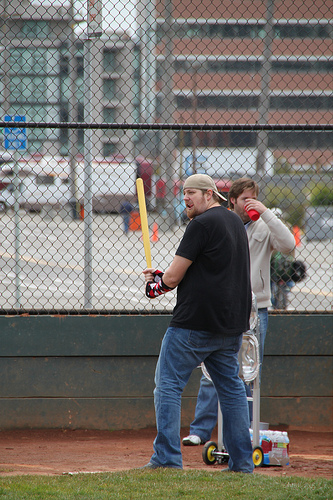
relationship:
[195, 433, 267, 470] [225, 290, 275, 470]
wheel on a dolly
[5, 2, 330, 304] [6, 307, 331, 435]
fence over a wall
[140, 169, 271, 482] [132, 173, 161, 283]
guy holding bat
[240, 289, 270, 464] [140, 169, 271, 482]
handtruck behind man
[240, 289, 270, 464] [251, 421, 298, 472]
handtruck carrying water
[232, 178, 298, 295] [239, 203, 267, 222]
guy drinking from cup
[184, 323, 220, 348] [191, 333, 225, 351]
pocket on back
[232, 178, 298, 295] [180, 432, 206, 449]
man has shoe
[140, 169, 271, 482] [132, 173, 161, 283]
man holding bat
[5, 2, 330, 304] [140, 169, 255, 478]
fence behind guy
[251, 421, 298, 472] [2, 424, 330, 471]
bottles are on ground